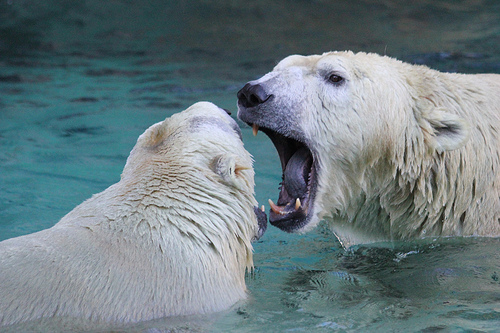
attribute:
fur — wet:
[374, 52, 498, 243]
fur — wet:
[140, 139, 264, 298]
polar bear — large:
[4, 97, 259, 330]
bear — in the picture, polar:
[237, 49, 499, 249]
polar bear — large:
[237, 50, 499, 250]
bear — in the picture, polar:
[3, 102, 270, 327]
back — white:
[49, 199, 167, 268]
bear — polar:
[170, 19, 485, 259]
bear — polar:
[14, 84, 281, 323]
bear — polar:
[211, 44, 485, 267]